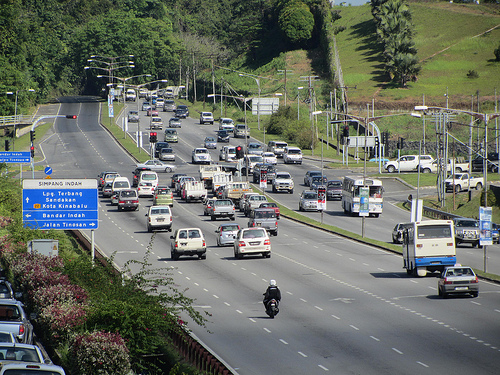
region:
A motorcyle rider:
[262, 278, 284, 317]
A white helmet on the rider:
[268, 279, 278, 286]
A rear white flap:
[417, 267, 427, 277]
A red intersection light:
[70, 113, 77, 120]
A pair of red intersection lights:
[148, 130, 156, 135]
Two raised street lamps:
[408, 103, 428, 118]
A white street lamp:
[310, 110, 322, 116]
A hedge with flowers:
[35, 280, 73, 307]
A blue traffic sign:
[42, 166, 52, 175]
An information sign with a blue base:
[26, 188, 91, 225]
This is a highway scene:
[5, 5, 495, 368]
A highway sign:
[21, 177, 101, 263]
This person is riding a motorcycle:
[261, 277, 283, 320]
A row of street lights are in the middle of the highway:
[83, 45, 171, 147]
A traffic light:
[146, 128, 158, 158]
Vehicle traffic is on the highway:
[96, 85, 482, 321]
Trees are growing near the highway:
[1, 0, 191, 110]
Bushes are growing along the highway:
[0, 242, 209, 374]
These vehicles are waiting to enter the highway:
[382, 151, 485, 193]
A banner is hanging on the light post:
[314, 180, 329, 220]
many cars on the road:
[15, 7, 491, 342]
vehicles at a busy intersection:
[30, 30, 484, 342]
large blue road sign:
[17, 173, 97, 235]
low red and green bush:
[69, 321, 131, 373]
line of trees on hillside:
[354, 1, 472, 113]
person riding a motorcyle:
[257, 275, 282, 319]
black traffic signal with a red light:
[148, 130, 157, 142]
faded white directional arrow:
[330, 293, 354, 306]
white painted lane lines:
[240, 310, 283, 345]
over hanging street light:
[412, 102, 486, 123]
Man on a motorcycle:
[256, 278, 292, 328]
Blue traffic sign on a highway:
[21, 173, 102, 236]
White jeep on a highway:
[231, 220, 279, 261]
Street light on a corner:
[308, 109, 385, 178]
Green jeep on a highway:
[151, 184, 174, 215]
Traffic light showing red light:
[146, 130, 161, 143]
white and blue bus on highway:
[397, 215, 459, 272]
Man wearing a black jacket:
[262, 282, 280, 300]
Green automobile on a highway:
[163, 125, 179, 145]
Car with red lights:
[116, 196, 140, 208]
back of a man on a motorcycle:
[262, 278, 282, 318]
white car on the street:
[170, 225, 207, 260]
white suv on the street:
[234, 226, 270, 258]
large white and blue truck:
[400, 219, 455, 273]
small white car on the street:
[437, 265, 477, 296]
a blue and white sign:
[20, 178, 97, 228]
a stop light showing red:
[65, 114, 79, 119]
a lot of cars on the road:
[100, 160, 280, 231]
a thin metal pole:
[90, 231, 95, 268]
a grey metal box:
[26, 237, 58, 259]